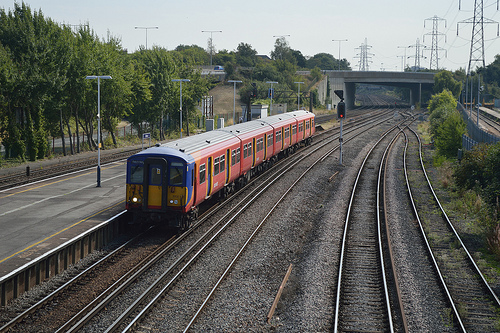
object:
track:
[23, 239, 171, 331]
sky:
[5, 2, 497, 70]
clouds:
[429, 14, 495, 64]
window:
[128, 161, 145, 183]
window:
[169, 162, 185, 187]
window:
[230, 150, 240, 163]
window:
[276, 131, 278, 143]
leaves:
[13, 26, 57, 88]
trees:
[0, 0, 73, 161]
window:
[199, 162, 206, 185]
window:
[213, 158, 219, 176]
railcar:
[126, 107, 315, 232]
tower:
[414, 12, 455, 78]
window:
[229, 150, 237, 166]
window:
[236, 148, 241, 163]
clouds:
[314, 9, 419, 61]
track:
[362, 217, 468, 327]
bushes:
[424, 87, 463, 158]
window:
[219, 154, 226, 172]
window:
[255, 137, 265, 152]